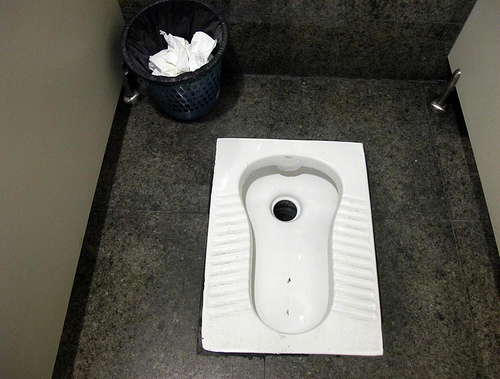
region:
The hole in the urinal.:
[274, 197, 298, 218]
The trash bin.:
[122, 11, 233, 127]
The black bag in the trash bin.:
[122, 4, 228, 80]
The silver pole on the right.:
[430, 64, 465, 119]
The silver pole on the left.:
[116, 62, 135, 114]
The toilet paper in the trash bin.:
[147, 28, 205, 70]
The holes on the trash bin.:
[140, 74, 224, 110]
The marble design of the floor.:
[77, 87, 498, 377]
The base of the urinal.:
[247, 158, 332, 336]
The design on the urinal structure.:
[197, 132, 379, 355]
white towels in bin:
[146, 44, 233, 89]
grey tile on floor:
[98, 281, 167, 332]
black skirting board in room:
[39, 140, 123, 377]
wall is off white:
[0, 68, 69, 375]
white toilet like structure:
[202, 145, 412, 377]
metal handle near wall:
[415, 67, 459, 121]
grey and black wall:
[255, 10, 416, 61]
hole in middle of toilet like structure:
[264, 169, 319, 251]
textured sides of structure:
[170, 188, 405, 333]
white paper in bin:
[142, 27, 197, 75]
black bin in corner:
[105, 1, 226, 102]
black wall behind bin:
[280, 19, 415, 74]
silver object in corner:
[426, 48, 478, 129]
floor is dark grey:
[105, 218, 192, 343]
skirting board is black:
[51, 143, 126, 373]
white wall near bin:
[18, 30, 90, 138]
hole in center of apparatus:
[264, 190, 318, 230]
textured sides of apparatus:
[196, 181, 373, 317]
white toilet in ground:
[200, 138, 382, 353]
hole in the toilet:
[282, 201, 297, 221]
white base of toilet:
[255, 159, 343, 333]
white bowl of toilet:
[263, 158, 332, 308]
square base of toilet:
[199, 133, 371, 350]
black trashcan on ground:
[126, 10, 224, 120]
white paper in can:
[158, 28, 205, 82]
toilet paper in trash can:
[126, 37, 200, 77]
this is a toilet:
[198, 122, 388, 363]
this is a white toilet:
[201, 125, 380, 358]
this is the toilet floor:
[122, 135, 182, 373]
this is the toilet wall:
[5, 10, 60, 340]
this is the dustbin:
[117, 3, 242, 118]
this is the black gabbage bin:
[125, 22, 147, 79]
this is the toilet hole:
[270, 190, 301, 221]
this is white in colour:
[165, 41, 190, 69]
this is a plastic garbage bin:
[117, 12, 229, 127]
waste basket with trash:
[113, 18, 238, 126]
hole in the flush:
[267, 191, 297, 226]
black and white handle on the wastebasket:
[118, 72, 138, 107]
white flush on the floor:
[205, 129, 375, 356]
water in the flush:
[278, 260, 310, 290]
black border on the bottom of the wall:
[87, 193, 103, 244]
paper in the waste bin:
[157, 30, 200, 72]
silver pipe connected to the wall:
[422, 68, 460, 120]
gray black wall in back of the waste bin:
[233, 10, 284, 48]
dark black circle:
[270, 196, 298, 221]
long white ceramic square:
[201, 129, 390, 359]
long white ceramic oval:
[235, 152, 344, 329]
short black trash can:
[117, 2, 226, 122]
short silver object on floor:
[430, 61, 468, 121]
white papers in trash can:
[152, 28, 212, 68]